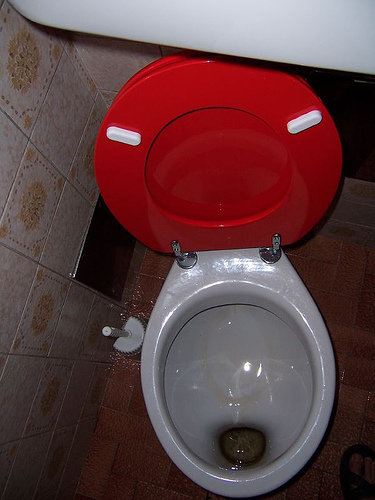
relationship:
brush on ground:
[101, 315, 147, 357] [63, 172, 373, 497]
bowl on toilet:
[137, 248, 335, 498] [84, 42, 352, 498]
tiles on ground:
[74, 235, 374, 498] [63, 172, 373, 497]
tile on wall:
[55, 424, 98, 500] [0, 0, 147, 499]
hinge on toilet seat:
[170, 244, 199, 269] [92, 57, 343, 259]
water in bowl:
[222, 425, 256, 451] [137, 248, 335, 498]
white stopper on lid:
[99, 115, 144, 149] [91, 47, 342, 249]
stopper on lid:
[289, 110, 322, 134] [85, 58, 352, 257]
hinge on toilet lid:
[170, 244, 216, 274] [109, 70, 353, 251]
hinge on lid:
[259, 234, 283, 264] [95, 51, 344, 251]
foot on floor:
[341, 445, 373, 497] [339, 440, 373, 500]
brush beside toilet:
[70, 291, 166, 391] [55, 84, 339, 499]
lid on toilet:
[95, 72, 341, 248] [84, 42, 352, 498]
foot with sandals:
[345, 451, 373, 497] [338, 444, 375, 497]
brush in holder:
[101, 315, 147, 357] [111, 316, 143, 355]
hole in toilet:
[216, 424, 266, 467] [84, 42, 352, 498]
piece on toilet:
[283, 112, 327, 139] [146, 169, 343, 427]